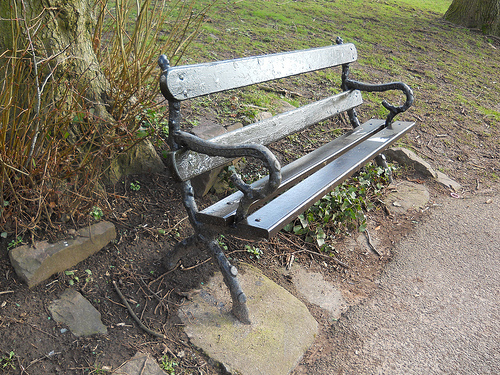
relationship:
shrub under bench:
[285, 148, 394, 257] [142, 33, 419, 323]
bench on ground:
[157, 35, 409, 325] [0, 0, 498, 372]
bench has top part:
[157, 35, 409, 325] [159, 45, 361, 98]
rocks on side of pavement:
[148, 250, 375, 362] [175, 268, 323, 373]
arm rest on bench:
[173, 127, 282, 219] [116, 36, 418, 324]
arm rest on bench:
[341, 72, 416, 127] [116, 36, 418, 324]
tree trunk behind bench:
[26, 83, 112, 201] [151, 43, 405, 255]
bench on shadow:
[168, 34, 398, 319] [347, 119, 405, 152]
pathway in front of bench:
[304, 200, 473, 348] [147, 46, 439, 266]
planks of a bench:
[166, 44, 408, 204] [159, 41, 416, 236]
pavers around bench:
[165, 248, 348, 370] [123, 48, 464, 255]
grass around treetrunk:
[1, 1, 208, 231] [3, 5, 162, 179]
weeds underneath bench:
[293, 168, 406, 249] [104, 42, 442, 322]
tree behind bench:
[2, 1, 162, 208] [157, 35, 409, 325]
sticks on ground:
[73, 261, 214, 343] [148, 270, 169, 302]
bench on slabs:
[178, 44, 380, 256] [181, 264, 321, 371]